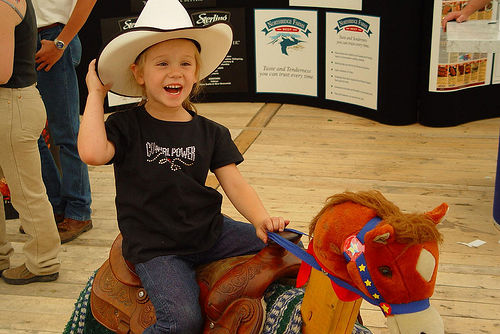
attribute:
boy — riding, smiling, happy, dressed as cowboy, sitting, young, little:
[75, 1, 293, 333]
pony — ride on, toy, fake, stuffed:
[59, 189, 447, 333]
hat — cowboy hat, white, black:
[94, 0, 235, 100]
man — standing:
[21, 0, 100, 248]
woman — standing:
[3, 1, 60, 287]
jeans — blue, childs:
[128, 214, 274, 334]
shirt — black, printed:
[101, 100, 247, 265]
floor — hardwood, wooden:
[5, 88, 499, 334]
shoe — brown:
[56, 215, 95, 247]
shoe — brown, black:
[1, 261, 62, 285]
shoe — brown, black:
[1, 253, 13, 274]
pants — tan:
[0, 82, 69, 277]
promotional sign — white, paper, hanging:
[325, 8, 381, 112]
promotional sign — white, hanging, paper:
[252, 7, 321, 101]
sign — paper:
[423, 2, 499, 97]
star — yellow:
[357, 259, 368, 274]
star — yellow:
[363, 277, 375, 288]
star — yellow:
[370, 292, 383, 302]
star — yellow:
[379, 301, 392, 315]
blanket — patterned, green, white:
[58, 263, 310, 333]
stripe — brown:
[200, 102, 284, 191]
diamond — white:
[412, 244, 438, 286]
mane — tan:
[306, 188, 448, 250]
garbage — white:
[455, 237, 487, 249]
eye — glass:
[379, 266, 391, 276]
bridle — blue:
[341, 211, 433, 316]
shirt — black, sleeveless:
[1, 1, 40, 92]